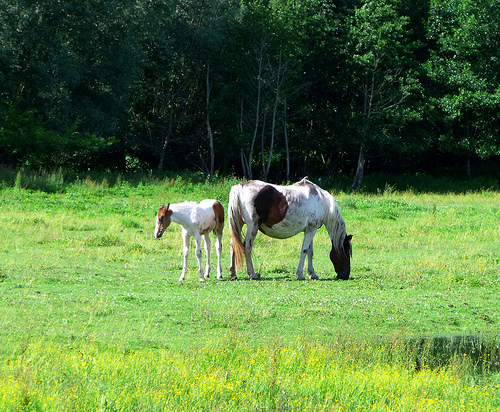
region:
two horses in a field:
[134, 169, 362, 299]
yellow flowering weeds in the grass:
[72, 353, 382, 405]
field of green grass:
[52, 259, 221, 341]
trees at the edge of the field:
[54, 41, 354, 176]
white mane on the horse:
[320, 189, 345, 246]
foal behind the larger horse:
[143, 190, 230, 284]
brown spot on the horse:
[249, 180, 291, 232]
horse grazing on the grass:
[224, 175, 361, 290]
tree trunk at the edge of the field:
[348, 157, 373, 193]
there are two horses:
[128, 138, 451, 363]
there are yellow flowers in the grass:
[50, 339, 488, 410]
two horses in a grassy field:
[136, 115, 481, 372]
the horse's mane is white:
[283, 169, 370, 257]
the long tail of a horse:
[217, 181, 255, 277]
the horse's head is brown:
[320, 223, 374, 302]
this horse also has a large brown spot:
[201, 185, 238, 248]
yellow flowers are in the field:
[4, 338, 472, 409]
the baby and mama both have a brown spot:
[204, 172, 294, 242]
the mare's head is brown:
[328, 233, 356, 280]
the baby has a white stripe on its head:
[151, 203, 173, 240]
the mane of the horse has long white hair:
[323, 189, 347, 256]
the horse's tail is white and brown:
[219, 179, 256, 271]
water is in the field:
[323, 321, 498, 386]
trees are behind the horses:
[8, 5, 496, 291]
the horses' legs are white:
[170, 240, 325, 288]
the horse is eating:
[227, 172, 387, 304]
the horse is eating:
[320, 215, 382, 314]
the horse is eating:
[328, 222, 380, 305]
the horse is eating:
[311, 216, 386, 300]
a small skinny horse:
[112, 178, 243, 291]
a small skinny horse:
[142, 180, 237, 294]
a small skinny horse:
[139, 166, 246, 318]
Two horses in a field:
[146, 180, 357, 282]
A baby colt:
[153, 196, 230, 281]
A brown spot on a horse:
[252, 184, 292, 229]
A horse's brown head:
[328, 227, 353, 280]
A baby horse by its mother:
[152, 179, 359, 282]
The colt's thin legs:
[172, 232, 227, 277]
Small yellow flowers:
[0, 337, 445, 409]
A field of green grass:
[0, 172, 499, 338]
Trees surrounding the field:
[0, 0, 497, 193]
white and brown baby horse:
[155, 198, 223, 283]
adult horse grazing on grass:
[226, 179, 353, 279]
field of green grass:
[0, 190, 497, 410]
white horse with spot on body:
[226, 175, 351, 282]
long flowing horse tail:
[228, 185, 251, 269]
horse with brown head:
[155, 199, 222, 281]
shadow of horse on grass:
[223, 275, 350, 282]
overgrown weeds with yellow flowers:
[1, 344, 498, 409]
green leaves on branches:
[1, 1, 498, 170]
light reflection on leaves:
[245, 0, 498, 120]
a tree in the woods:
[418, 3, 496, 185]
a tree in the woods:
[334, 2, 424, 191]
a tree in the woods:
[291, 5, 351, 181]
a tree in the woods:
[277, 60, 294, 179]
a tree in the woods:
[236, 11, 316, 178]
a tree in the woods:
[226, 91, 253, 177]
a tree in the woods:
[158, 2, 245, 178]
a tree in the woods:
[131, 8, 201, 181]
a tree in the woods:
[3, 5, 134, 178]